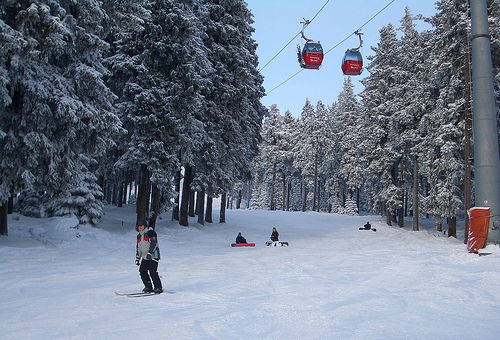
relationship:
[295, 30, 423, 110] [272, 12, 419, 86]
cars on rail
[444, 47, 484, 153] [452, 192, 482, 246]
pole with mat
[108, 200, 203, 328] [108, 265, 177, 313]
man wearing skis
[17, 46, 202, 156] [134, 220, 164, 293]
trees behind man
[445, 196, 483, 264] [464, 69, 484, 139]
mat leaning on pole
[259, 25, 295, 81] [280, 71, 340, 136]
sky on day